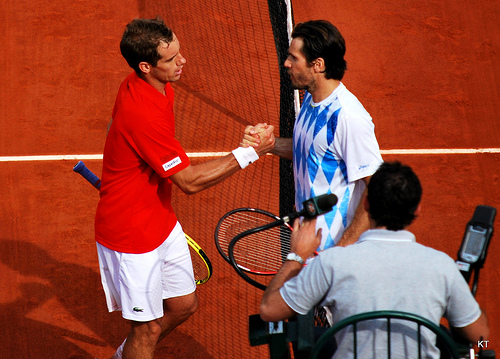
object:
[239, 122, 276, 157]
two hands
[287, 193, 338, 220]
microphone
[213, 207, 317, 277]
racket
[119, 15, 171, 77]
black hair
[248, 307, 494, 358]
chair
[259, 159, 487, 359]
man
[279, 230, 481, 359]
shirt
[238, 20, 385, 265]
player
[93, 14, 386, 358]
players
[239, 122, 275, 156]
hands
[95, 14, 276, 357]
man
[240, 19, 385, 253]
man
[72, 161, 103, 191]
handle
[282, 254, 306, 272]
clock wrist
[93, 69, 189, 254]
shirt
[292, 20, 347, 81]
black hair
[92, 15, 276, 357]
player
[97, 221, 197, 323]
shorts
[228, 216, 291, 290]
part